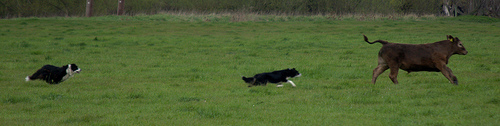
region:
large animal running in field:
[361, 25, 484, 100]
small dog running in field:
[237, 50, 347, 110]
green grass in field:
[105, 25, 195, 110]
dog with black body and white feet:
[230, 60, 312, 102]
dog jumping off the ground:
[23, 58, 106, 88]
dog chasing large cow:
[225, 38, 475, 92]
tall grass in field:
[185, 4, 369, 31]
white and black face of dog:
[67, 63, 88, 79]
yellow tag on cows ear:
[445, 32, 455, 44]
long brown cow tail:
[352, 24, 404, 54]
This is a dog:
[12, 49, 90, 91]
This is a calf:
[350, 29, 478, 89]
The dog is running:
[27, 59, 91, 95]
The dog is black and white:
[30, 48, 90, 93]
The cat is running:
[240, 63, 322, 106]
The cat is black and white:
[232, 59, 324, 106]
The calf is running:
[346, 20, 469, 86]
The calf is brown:
[359, 29, 468, 86]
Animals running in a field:
[3, 14, 487, 124]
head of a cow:
[443, 24, 475, 56]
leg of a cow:
[432, 59, 471, 84]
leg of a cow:
[388, 67, 416, 82]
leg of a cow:
[370, 68, 382, 83]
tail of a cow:
[356, 34, 385, 58]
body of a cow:
[369, 21, 436, 75]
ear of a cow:
[446, 32, 460, 44]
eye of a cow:
[456, 42, 465, 46]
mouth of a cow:
[460, 47, 471, 57]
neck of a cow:
[442, 35, 459, 60]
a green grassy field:
[0, 0, 498, 124]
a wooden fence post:
[81, 0, 92, 20]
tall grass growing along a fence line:
[156, 9, 439, 25]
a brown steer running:
[357, 30, 467, 85]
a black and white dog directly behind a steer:
[235, 61, 301, 91]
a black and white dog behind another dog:
[22, 56, 82, 89]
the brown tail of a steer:
[361, 31, 388, 49]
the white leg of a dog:
[288, 77, 298, 90]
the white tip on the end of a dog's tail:
[22, 72, 27, 84]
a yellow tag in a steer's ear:
[445, 34, 455, 46]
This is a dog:
[20, 51, 88, 95]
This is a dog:
[240, 57, 313, 104]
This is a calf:
[357, 29, 475, 91]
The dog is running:
[22, 53, 92, 98]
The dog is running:
[244, 62, 302, 94]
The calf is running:
[350, 25, 471, 92]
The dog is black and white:
[24, 53, 86, 88]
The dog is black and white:
[235, 53, 305, 98]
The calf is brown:
[354, 28, 478, 94]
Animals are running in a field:
[5, 13, 498, 119]